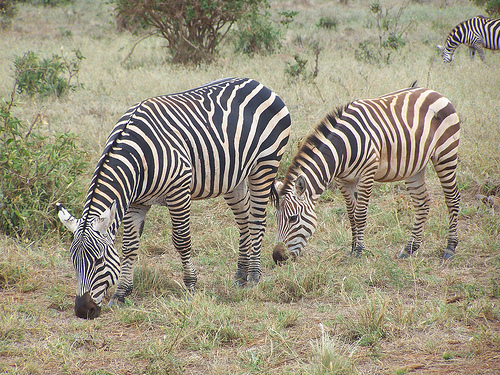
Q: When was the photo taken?
A: Daytime.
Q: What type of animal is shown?
A: Zebras.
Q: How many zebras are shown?
A: Three.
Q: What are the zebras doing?
A: Eating.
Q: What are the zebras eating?
A: Grass.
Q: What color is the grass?
A: Brown.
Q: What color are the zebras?
A: Black and white.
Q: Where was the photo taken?
A: At the zoo.